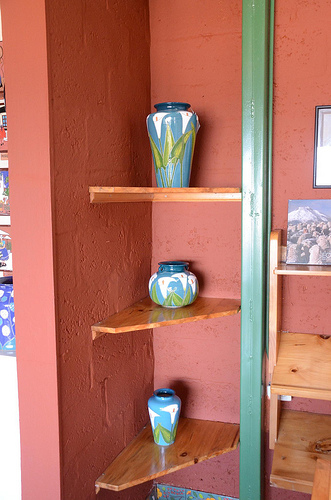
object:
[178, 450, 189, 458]
knot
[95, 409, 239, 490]
shelf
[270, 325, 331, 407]
shelf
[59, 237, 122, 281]
holes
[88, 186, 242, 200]
shelf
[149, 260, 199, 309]
vase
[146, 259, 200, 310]
pot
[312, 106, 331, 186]
picture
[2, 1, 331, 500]
brick wall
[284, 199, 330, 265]
picture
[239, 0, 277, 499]
green post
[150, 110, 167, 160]
lilies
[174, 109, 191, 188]
lilies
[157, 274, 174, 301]
lilies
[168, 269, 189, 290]
lilies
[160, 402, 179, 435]
lilies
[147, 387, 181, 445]
vase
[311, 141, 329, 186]
light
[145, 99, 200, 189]
vase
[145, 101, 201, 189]
flower pot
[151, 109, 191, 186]
flowers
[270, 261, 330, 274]
shelf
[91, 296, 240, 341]
shelf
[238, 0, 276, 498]
beam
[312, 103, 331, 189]
frame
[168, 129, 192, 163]
leaf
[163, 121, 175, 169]
leaf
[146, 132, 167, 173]
leaf